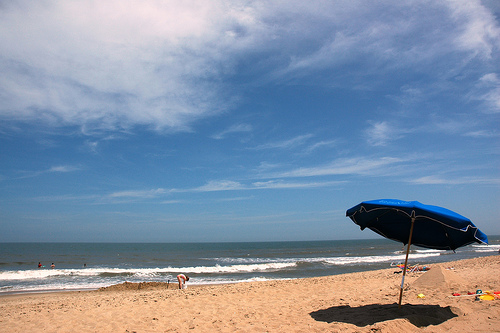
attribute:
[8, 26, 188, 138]
sky — blue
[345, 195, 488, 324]
umbrella — blue 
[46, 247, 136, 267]
water — body